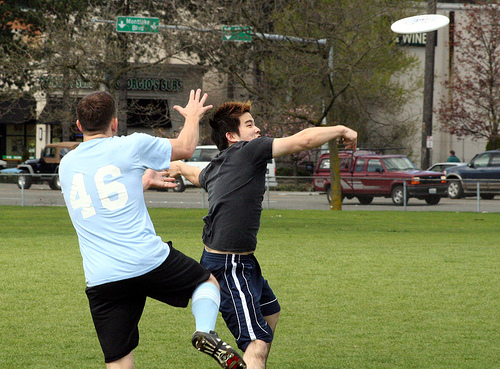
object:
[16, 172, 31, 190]
tire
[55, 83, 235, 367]
man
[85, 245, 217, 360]
shorts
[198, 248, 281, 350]
shorts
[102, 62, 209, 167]
store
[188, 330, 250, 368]
wearing cleats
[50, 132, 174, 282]
shirt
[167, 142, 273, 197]
van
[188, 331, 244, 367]
cleat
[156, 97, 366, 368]
man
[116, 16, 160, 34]
sign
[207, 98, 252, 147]
hair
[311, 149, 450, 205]
pick-up truck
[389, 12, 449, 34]
frisbee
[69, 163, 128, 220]
shirt number/46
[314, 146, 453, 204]
pick up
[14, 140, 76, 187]
jeep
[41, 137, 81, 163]
brown top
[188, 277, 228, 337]
shin sock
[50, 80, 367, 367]
men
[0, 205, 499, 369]
grass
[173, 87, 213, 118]
mans hand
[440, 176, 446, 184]
light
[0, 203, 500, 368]
field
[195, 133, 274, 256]
shirt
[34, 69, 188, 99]
words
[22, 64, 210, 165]
building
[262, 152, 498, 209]
lot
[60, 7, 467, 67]
air